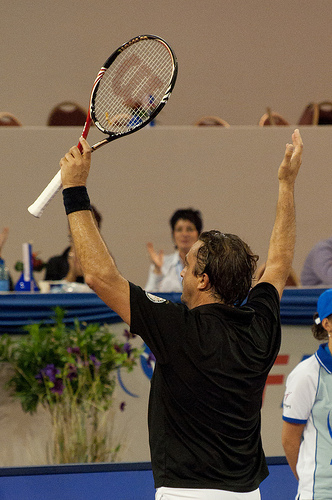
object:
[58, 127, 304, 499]
man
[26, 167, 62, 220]
grip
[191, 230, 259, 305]
hair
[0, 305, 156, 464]
plant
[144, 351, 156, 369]
blooms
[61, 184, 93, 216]
band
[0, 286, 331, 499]
wall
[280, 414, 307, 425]
stripe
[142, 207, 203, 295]
woman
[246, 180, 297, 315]
arm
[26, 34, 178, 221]
racket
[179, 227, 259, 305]
top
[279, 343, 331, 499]
shirt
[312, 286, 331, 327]
cap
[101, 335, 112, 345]
leaf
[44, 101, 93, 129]
chair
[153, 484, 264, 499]
shorts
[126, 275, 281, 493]
shirt